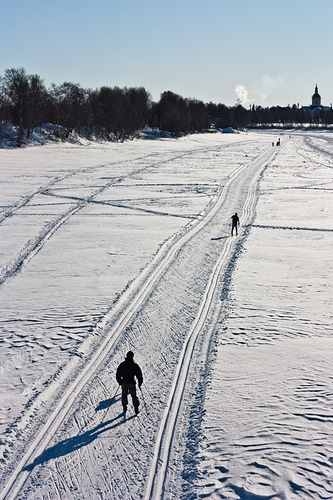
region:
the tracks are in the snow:
[174, 254, 209, 451]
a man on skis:
[115, 347, 142, 415]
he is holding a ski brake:
[138, 382, 163, 414]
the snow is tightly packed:
[257, 350, 321, 441]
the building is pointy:
[306, 78, 326, 115]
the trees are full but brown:
[27, 78, 201, 133]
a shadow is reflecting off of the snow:
[18, 427, 112, 475]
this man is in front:
[225, 211, 244, 236]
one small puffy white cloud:
[227, 82, 256, 107]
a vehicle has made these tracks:
[12, 145, 122, 222]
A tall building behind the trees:
[297, 78, 331, 126]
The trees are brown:
[4, 58, 260, 137]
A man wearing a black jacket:
[109, 346, 158, 437]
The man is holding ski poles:
[98, 350, 170, 438]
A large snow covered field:
[18, 134, 329, 427]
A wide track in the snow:
[67, 125, 302, 455]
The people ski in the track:
[110, 133, 297, 415]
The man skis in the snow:
[96, 339, 162, 424]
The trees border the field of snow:
[6, 67, 327, 130]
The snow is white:
[41, 157, 187, 315]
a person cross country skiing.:
[71, 334, 199, 454]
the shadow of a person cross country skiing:
[7, 392, 143, 479]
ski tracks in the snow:
[138, 319, 186, 371]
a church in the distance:
[285, 68, 328, 120]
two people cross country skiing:
[44, 161, 319, 443]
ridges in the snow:
[249, 405, 322, 499]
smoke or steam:
[218, 44, 256, 118]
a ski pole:
[133, 385, 159, 421]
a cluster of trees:
[42, 68, 228, 159]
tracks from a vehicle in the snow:
[106, 247, 244, 331]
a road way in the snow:
[143, 133, 291, 412]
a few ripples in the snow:
[239, 407, 317, 494]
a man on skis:
[91, 348, 161, 431]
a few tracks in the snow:
[60, 141, 224, 234]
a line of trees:
[13, 67, 238, 150]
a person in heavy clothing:
[107, 352, 159, 421]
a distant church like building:
[297, 82, 332, 129]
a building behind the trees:
[276, 82, 327, 134]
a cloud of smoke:
[224, 75, 260, 114]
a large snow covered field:
[57, 114, 315, 343]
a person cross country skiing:
[112, 340, 154, 418]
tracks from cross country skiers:
[66, 425, 159, 498]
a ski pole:
[142, 379, 165, 417]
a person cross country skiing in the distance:
[207, 201, 249, 246]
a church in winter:
[294, 76, 331, 122]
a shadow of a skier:
[14, 417, 157, 478]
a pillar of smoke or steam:
[213, 62, 265, 113]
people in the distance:
[267, 132, 301, 151]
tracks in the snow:
[39, 166, 160, 246]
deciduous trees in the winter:
[16, 69, 195, 164]